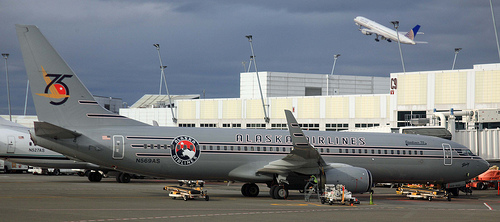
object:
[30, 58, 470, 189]
gray plane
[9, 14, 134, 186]
tail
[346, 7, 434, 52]
plane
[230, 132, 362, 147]
letters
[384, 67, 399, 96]
numbers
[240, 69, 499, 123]
building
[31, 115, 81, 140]
wing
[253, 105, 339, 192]
wing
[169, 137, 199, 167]
symbol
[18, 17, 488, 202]
trash bins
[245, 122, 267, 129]
window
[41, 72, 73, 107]
75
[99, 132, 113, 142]
flag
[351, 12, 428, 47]
white plane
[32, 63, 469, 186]
airplane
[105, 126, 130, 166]
door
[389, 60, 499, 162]
building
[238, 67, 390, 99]
building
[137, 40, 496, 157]
airport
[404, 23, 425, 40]
wing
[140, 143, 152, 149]
windows